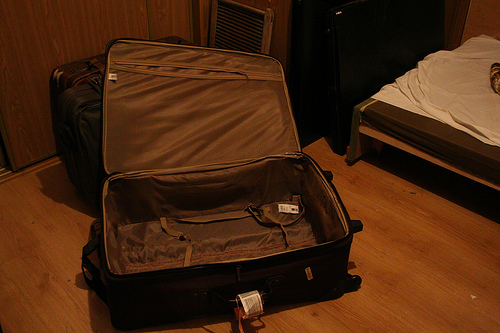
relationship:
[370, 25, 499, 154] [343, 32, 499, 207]
sheet on bed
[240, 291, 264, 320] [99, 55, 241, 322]
tag on suitcase